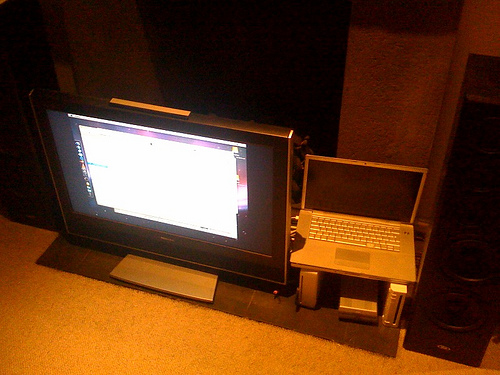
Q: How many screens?
A: Two.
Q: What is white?
A: The page on the large monitor.